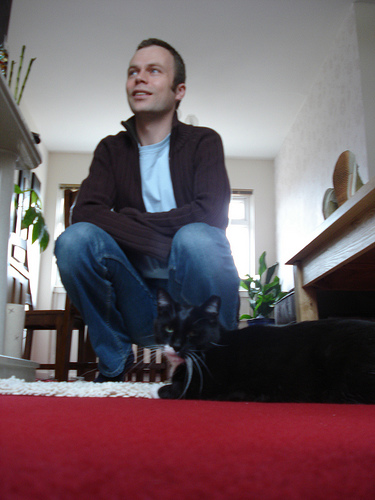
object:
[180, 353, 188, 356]
spot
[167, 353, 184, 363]
mouth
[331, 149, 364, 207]
plates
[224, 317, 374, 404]
body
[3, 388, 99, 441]
floor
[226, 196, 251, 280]
window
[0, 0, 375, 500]
room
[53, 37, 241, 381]
guy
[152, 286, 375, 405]
cat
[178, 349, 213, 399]
whiskers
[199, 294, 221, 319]
ear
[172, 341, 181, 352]
nose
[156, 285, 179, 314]
ear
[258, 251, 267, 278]
leaf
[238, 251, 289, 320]
plant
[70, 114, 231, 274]
sweater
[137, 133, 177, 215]
shirt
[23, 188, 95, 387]
chair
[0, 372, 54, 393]
cloth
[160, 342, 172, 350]
patch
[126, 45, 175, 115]
face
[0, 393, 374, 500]
carpet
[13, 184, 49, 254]
plant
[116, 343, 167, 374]
whiskers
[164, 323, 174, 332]
eye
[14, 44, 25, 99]
bamboo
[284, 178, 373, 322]
table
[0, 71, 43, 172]
mantle